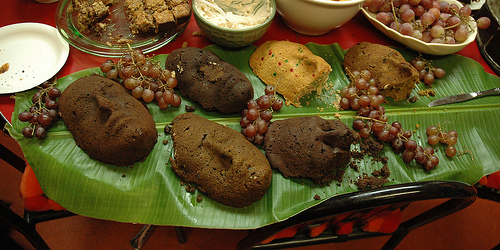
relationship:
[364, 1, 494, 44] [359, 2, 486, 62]
grapes in bowl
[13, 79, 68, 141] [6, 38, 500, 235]
grapes on leaf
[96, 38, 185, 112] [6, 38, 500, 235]
grapes on leaf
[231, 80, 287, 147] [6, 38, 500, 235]
grapes on leaf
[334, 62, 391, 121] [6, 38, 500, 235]
grapes on leaf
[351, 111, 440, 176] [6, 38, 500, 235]
grapes on leaf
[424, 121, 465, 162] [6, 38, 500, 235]
grapes on leaf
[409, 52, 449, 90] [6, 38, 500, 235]
grapes on leaf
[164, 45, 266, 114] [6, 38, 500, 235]
cookies on leaf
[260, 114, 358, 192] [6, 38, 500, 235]
cookies on leaf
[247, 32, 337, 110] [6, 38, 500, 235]
cookies on leaf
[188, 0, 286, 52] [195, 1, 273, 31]
bowl of frosting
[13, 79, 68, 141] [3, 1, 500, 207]
grapes on table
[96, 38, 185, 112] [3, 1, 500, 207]
grapes on table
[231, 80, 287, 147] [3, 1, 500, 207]
grapes on table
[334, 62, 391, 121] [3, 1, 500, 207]
grapes on table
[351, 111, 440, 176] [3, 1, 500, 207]
grapes on table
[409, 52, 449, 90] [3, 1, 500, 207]
grapes on table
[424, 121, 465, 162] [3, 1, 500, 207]
grapes on table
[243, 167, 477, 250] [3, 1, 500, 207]
chair at table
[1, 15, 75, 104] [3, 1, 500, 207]
plate on table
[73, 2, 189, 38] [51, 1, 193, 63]
brownies on dish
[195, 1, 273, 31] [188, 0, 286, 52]
frosting in bowl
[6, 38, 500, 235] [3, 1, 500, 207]
leaf on table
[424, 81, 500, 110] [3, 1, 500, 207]
knife on table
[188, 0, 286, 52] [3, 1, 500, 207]
bowl on table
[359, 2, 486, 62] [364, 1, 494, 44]
bowl holding grapes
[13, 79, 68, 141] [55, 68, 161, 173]
grapes by cookies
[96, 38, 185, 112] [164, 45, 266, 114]
grapes by cookies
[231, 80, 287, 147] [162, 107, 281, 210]
grapes by cookies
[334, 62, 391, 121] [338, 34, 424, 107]
grapes by cookies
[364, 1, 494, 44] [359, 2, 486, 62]
grapes inside bowl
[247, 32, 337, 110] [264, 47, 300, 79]
cookies has dots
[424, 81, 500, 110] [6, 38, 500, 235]
knife on leaf